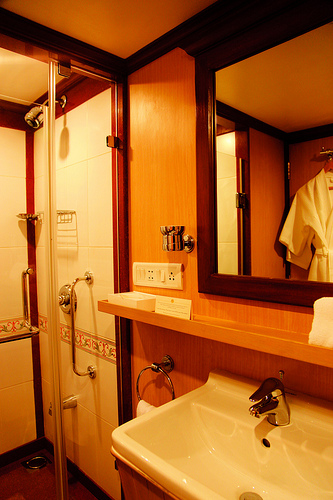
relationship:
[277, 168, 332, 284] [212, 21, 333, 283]
robe reflected in mirror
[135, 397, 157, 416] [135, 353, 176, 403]
towel hanging on towel holder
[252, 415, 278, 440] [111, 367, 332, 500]
shadow on top of sink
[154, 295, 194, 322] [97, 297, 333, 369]
sign on top of shelf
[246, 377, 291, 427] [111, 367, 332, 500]
faucet on top of sink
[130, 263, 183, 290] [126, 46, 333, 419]
outlet on side of wall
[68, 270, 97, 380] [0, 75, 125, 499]
handle inside of shower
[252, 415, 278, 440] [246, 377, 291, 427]
shadow from faucet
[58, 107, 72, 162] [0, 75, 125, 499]
shadow on side of shower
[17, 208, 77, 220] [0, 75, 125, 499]
soap tray hanging in shower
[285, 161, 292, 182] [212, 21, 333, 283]
door hinge reflected in mirror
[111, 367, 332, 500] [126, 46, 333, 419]
sink against wall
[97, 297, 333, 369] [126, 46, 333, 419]
shelf hanging on wall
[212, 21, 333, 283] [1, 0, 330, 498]
mirror in a bathroom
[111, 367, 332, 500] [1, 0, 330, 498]
sink in a bathroom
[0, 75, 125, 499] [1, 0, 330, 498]
shower in a bathroom